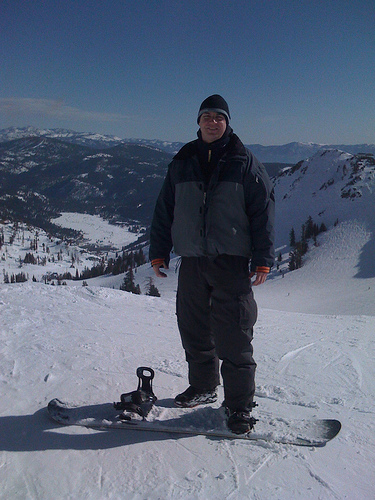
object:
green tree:
[121, 267, 140, 297]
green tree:
[72, 266, 83, 280]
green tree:
[133, 280, 143, 293]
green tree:
[274, 250, 284, 262]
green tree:
[121, 266, 135, 292]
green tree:
[135, 281, 141, 293]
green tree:
[72, 265, 82, 280]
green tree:
[76, 264, 81, 278]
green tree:
[145, 280, 161, 297]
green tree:
[115, 265, 136, 299]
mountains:
[0, 126, 375, 230]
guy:
[149, 90, 275, 439]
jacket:
[175, 258, 257, 410]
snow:
[29, 299, 113, 372]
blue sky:
[33, 21, 303, 91]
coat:
[148, 124, 288, 275]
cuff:
[246, 251, 274, 276]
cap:
[195, 95, 233, 124]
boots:
[172, 383, 218, 410]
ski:
[44, 363, 342, 449]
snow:
[271, 323, 367, 410]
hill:
[0, 117, 375, 225]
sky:
[0, 0, 375, 146]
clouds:
[0, 72, 375, 144]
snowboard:
[45, 366, 341, 447]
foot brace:
[110, 367, 157, 424]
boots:
[219, 393, 258, 440]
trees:
[49, 224, 130, 297]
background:
[0, 0, 375, 402]